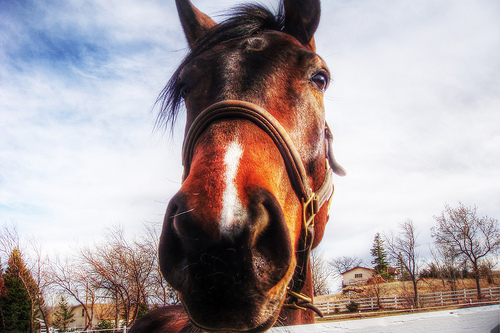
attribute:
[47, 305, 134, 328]
barn — pictured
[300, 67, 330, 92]
eye — calm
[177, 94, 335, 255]
horse's bridle — pictured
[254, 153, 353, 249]
buckle — brass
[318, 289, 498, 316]
fence — white, protecting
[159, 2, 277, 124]
hair — black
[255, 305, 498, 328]
railing — white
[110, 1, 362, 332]
horse — close up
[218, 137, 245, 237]
patch — white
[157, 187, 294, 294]
nose — horse's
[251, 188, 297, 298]
nostril — horse's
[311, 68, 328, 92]
eye — brown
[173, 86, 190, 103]
eye — brown